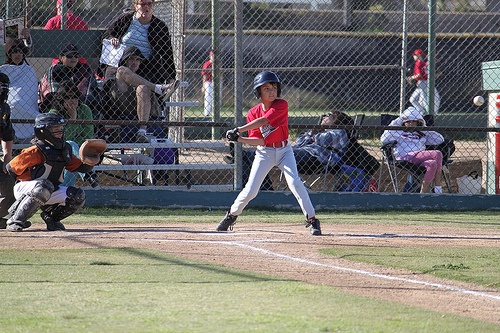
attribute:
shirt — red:
[251, 99, 305, 148]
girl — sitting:
[390, 105, 443, 155]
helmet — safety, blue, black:
[237, 56, 291, 104]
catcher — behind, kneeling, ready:
[19, 107, 123, 206]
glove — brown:
[75, 136, 118, 175]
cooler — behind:
[137, 125, 165, 157]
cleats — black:
[218, 191, 366, 265]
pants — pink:
[411, 136, 450, 183]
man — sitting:
[108, 20, 180, 145]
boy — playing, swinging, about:
[209, 70, 296, 199]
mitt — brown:
[73, 140, 149, 201]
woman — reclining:
[300, 100, 362, 174]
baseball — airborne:
[449, 69, 496, 121]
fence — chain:
[303, 4, 386, 77]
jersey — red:
[226, 100, 361, 178]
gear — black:
[24, 181, 71, 242]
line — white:
[272, 237, 360, 277]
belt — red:
[260, 127, 299, 152]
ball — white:
[443, 69, 497, 127]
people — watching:
[32, 37, 104, 86]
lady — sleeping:
[306, 90, 404, 213]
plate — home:
[70, 206, 148, 254]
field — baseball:
[34, 21, 476, 279]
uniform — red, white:
[401, 60, 431, 112]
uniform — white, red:
[197, 64, 227, 116]